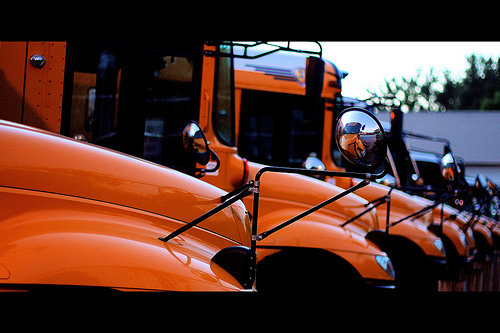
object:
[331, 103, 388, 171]
mirror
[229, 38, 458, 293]
bus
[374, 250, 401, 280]
light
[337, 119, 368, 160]
reflection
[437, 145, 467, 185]
frame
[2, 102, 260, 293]
schoolbus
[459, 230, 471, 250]
signal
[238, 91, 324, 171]
door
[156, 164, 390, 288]
bracket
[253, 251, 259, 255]
bolt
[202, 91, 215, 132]
handle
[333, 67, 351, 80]
reflector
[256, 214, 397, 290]
fender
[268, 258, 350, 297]
wheel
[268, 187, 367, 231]
shadow